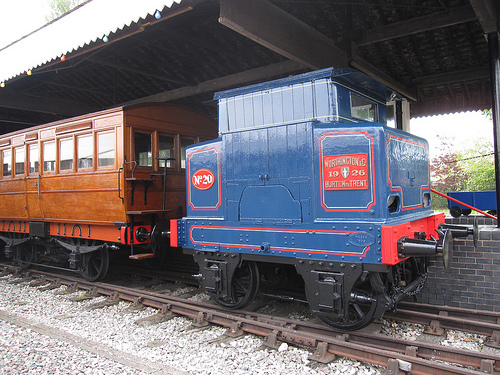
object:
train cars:
[0, 73, 444, 310]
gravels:
[276, 341, 289, 350]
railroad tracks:
[0, 257, 499, 374]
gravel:
[439, 330, 490, 351]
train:
[0, 67, 479, 331]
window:
[96, 131, 118, 173]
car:
[0, 97, 218, 281]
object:
[421, 187, 498, 220]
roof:
[0, 1, 499, 126]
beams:
[94, 7, 476, 111]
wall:
[414, 229, 499, 314]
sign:
[188, 168, 214, 192]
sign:
[321, 153, 371, 193]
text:
[323, 178, 367, 190]